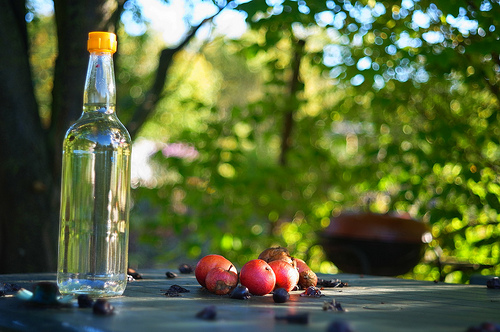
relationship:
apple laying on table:
[207, 263, 237, 294] [1, 267, 500, 328]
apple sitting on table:
[242, 259, 278, 293] [1, 267, 500, 328]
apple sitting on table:
[268, 257, 299, 294] [1, 267, 500, 328]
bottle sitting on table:
[57, 33, 134, 298] [1, 267, 500, 328]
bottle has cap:
[57, 33, 134, 298] [85, 30, 118, 53]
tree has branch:
[2, 3, 500, 283] [125, 1, 231, 141]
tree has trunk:
[2, 3, 500, 283] [1, 130, 76, 273]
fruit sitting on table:
[195, 247, 319, 295] [1, 267, 500, 328]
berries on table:
[4, 261, 500, 330] [1, 267, 500, 328]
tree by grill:
[2, 3, 500, 283] [312, 193, 434, 275]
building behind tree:
[129, 140, 216, 214] [2, 3, 500, 283]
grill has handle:
[312, 193, 434, 275] [366, 189, 398, 212]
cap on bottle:
[85, 30, 118, 53] [57, 33, 134, 298]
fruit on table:
[195, 247, 319, 295] [1, 267, 500, 328]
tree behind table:
[2, 3, 500, 283] [1, 267, 500, 328]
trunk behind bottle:
[1, 130, 76, 273] [57, 33, 134, 298]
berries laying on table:
[4, 261, 500, 330] [1, 267, 500, 328]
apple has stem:
[207, 263, 237, 294] [227, 262, 235, 272]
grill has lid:
[312, 193, 434, 275] [316, 189, 439, 244]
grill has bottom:
[312, 193, 434, 275] [315, 231, 427, 275]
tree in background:
[2, 3, 500, 283] [2, 1, 498, 271]